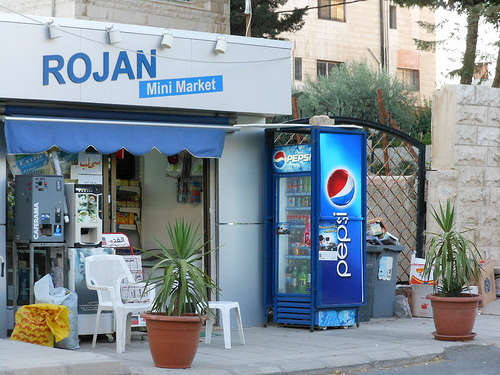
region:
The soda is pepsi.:
[260, 121, 367, 333]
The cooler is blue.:
[265, 130, 362, 332]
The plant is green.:
[145, 226, 210, 316]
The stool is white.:
[194, 296, 246, 350]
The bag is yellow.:
[11, 301, 74, 351]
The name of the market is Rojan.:
[33, 43, 234, 106]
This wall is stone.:
[448, 92, 499, 222]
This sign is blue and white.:
[7, 22, 267, 107]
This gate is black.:
[282, 129, 418, 310]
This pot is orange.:
[135, 306, 211, 368]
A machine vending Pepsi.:
[261, 121, 374, 333]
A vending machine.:
[266, 118, 370, 334]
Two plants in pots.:
[131, 196, 487, 368]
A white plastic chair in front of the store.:
[83, 243, 159, 354]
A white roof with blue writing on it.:
[4, 11, 301, 118]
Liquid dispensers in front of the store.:
[17, 166, 113, 253]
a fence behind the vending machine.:
[268, 114, 433, 288]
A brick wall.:
[420, 81, 498, 288]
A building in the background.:
[32, 0, 496, 135]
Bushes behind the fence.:
[267, 56, 446, 169]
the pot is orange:
[136, 306, 206, 367]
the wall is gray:
[452, 103, 494, 205]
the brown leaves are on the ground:
[367, 358, 445, 373]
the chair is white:
[81, 252, 152, 352]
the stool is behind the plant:
[201, 298, 255, 355]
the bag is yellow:
[2, 289, 76, 344]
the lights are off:
[95, 26, 245, 56]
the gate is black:
[376, 125, 430, 233]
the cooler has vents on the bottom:
[273, 297, 314, 327]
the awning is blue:
[7, 124, 249, 161]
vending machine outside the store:
[0, 21, 372, 336]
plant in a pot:
[417, 197, 489, 345]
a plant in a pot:
[130, 210, 225, 371]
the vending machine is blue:
[256, 122, 373, 336]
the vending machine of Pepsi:
[324, 159, 358, 293]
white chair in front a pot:
[76, 232, 208, 369]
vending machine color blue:
[259, 121, 372, 338]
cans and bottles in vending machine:
[277, 170, 313, 291]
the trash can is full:
[359, 214, 409, 319]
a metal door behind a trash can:
[357, 114, 431, 316]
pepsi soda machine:
[258, 120, 375, 334]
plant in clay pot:
[417, 194, 497, 344]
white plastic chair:
[77, 248, 157, 357]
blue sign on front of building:
[38, 47, 230, 107]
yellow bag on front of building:
[6, 298, 72, 350]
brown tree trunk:
[456, 5, 481, 85]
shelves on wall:
[116, 172, 142, 236]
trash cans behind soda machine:
[366, 213, 406, 324]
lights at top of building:
[40, 16, 230, 56]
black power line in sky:
[256, 2, 370, 14]